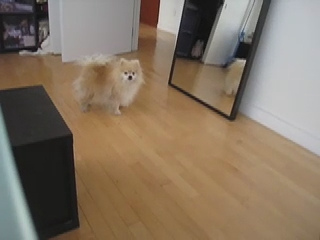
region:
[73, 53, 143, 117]
fluffy yellow dog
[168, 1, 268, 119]
mirror with brown frame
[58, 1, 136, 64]
open white door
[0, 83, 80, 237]
small black shelf system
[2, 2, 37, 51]
picture of cat in background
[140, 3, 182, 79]
open doorway into hall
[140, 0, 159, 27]
dark brown closed door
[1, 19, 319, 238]
light brown hard wood flooring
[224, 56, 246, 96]
reflection of fluffy dog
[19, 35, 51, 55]
wwhite cloth in the background on the floor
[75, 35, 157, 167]
the dog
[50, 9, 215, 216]
the dog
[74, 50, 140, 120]
a small tan dog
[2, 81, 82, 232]
a large black box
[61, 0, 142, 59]
a white door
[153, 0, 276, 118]
a mirror against a wall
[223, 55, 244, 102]
a reflection of the dog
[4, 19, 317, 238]
Hard wood flooring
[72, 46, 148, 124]
a Pomeranian on the floor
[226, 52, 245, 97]
the reflection of a Pomeranian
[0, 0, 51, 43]
a closet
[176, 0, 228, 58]
the reflection of the closet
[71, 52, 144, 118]
dog is small and fuzzy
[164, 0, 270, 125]
black mirror leans against wall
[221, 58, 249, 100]
dog's tail reflected in mirror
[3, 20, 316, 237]
light colored wooden floor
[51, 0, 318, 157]
room has white walls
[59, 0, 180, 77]
white door in room is open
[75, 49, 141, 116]
dog is standing on floor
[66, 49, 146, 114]
dog is beige and white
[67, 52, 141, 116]
dog is looking forward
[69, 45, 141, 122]
dog is by door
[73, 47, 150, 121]
a small brown dog on floor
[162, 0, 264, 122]
a floor standing mirror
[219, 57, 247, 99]
a reflection of dog in mirror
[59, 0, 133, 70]
a white open door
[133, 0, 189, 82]
an open doorway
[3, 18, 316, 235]
blonde hardwood flooring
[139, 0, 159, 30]
a closed brown door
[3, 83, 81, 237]
a black square box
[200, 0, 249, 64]
a reflection of a white door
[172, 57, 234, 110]
reflection of hardwood flooring